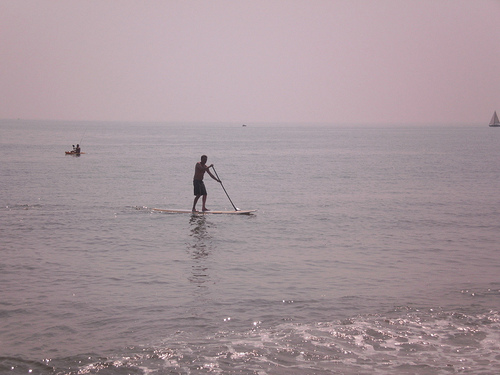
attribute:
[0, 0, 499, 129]
sky — overcast, soothing, gray, smoky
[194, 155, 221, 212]
man — balancing, standing, boarding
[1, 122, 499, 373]
water — coming, calm, sea, board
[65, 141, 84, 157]
people — sitting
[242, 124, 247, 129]
object — brown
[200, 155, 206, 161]
hair — short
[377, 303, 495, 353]
wave — small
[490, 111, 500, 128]
sailboat — couple